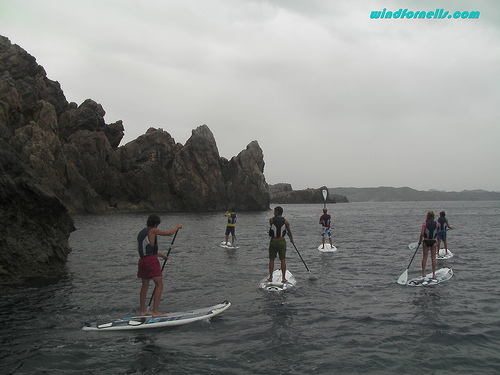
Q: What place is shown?
A: It is an ocean.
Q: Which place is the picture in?
A: It is at the ocean.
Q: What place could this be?
A: It is an ocean.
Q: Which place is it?
A: It is an ocean.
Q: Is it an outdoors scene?
A: Yes, it is outdoors.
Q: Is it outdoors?
A: Yes, it is outdoors.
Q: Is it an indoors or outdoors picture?
A: It is outdoors.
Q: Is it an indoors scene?
A: No, it is outdoors.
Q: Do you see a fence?
A: No, there are no fences.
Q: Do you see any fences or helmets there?
A: No, there are no fences or helmets.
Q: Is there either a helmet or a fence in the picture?
A: No, there are no fences or helmets.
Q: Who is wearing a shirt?
A: The man is wearing a shirt.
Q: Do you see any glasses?
A: No, there are no glasses.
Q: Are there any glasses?
A: No, there are no glasses.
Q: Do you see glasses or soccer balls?
A: No, there are no glasses or soccer balls.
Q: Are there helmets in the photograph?
A: No, there are no helmets.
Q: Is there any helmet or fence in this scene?
A: No, there are no helmets or fences.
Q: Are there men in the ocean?
A: Yes, there is a man in the ocean.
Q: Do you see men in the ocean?
A: Yes, there is a man in the ocean.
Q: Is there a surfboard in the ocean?
A: No, there is a man in the ocean.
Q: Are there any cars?
A: No, there are no cars.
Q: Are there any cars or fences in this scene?
A: No, there are no cars or fences.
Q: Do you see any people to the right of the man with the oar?
A: Yes, there are people to the right of the man.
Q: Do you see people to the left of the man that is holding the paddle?
A: No, the people are to the right of the man.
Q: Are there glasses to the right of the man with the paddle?
A: No, there are people to the right of the man.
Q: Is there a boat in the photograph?
A: No, there are no boats.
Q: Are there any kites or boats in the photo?
A: No, there are no boats or kites.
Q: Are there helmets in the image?
A: No, there are no helmets.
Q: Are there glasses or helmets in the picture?
A: No, there are no helmets or glasses.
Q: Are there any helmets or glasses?
A: No, there are no helmets or glasses.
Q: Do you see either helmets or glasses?
A: No, there are no helmets or glasses.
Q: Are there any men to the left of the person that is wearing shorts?
A: Yes, there is a man to the left of the person.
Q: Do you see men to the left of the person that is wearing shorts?
A: Yes, there is a man to the left of the person.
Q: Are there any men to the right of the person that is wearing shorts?
A: No, the man is to the left of the person.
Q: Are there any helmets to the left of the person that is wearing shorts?
A: No, there is a man to the left of the person.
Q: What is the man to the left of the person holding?
A: The man is holding the paddle.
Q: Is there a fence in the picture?
A: No, there are no fences.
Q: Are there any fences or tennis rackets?
A: No, there are no fences or tennis rackets.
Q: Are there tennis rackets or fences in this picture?
A: No, there are no fences or tennis rackets.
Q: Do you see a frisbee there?
A: No, there are no frisbees.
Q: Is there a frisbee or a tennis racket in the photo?
A: No, there are no frisbees or rackets.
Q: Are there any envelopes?
A: No, there are no envelopes.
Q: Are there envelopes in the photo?
A: No, there are no envelopes.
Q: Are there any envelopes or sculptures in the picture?
A: No, there are no envelopes or sculptures.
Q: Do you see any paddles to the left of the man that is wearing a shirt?
A: Yes, there is a paddle to the left of the man.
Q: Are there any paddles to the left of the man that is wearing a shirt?
A: Yes, there is a paddle to the left of the man.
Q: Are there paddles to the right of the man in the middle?
A: No, the paddle is to the left of the man.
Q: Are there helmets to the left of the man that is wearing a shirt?
A: No, there is a paddle to the left of the man.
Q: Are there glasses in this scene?
A: No, there are no glasses.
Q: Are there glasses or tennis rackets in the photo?
A: No, there are no glasses or tennis rackets.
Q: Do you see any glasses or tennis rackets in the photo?
A: No, there are no glasses or tennis rackets.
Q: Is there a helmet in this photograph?
A: No, there are no helmets.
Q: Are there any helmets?
A: No, there are no helmets.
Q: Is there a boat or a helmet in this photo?
A: No, there are no helmets or boats.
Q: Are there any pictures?
A: No, there are no pictures.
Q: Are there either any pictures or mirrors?
A: No, there are no pictures or mirrors.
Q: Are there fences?
A: No, there are no fences.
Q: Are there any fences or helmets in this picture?
A: No, there are no fences or helmets.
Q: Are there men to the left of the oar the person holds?
A: Yes, there is a man to the left of the oar.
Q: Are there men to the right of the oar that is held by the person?
A: No, the man is to the left of the oar.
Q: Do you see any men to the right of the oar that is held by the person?
A: No, the man is to the left of the oar.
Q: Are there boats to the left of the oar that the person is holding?
A: No, there is a man to the left of the paddle.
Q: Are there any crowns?
A: No, there are no crowns.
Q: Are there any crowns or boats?
A: No, there are no crowns or boats.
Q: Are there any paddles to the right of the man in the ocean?
A: Yes, there is a paddle to the right of the man.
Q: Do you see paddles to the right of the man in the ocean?
A: Yes, there is a paddle to the right of the man.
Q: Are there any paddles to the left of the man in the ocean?
A: No, the paddle is to the right of the man.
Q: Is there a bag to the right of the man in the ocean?
A: No, there is a paddle to the right of the man.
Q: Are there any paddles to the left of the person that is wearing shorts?
A: Yes, there is a paddle to the left of the person.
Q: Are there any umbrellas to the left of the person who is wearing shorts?
A: No, there is a paddle to the left of the person.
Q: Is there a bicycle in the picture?
A: No, there are no bicycles.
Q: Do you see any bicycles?
A: No, there are no bicycles.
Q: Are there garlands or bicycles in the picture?
A: No, there are no bicycles or garlands.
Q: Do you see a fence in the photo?
A: No, there are no fences.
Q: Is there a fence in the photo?
A: No, there are no fences.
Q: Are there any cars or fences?
A: No, there are no fences or cars.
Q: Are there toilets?
A: No, there are no toilets.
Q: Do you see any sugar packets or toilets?
A: No, there are no toilets or sugar packets.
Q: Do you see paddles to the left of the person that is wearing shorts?
A: Yes, there is a paddle to the left of the person.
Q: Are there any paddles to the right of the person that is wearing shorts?
A: No, the paddle is to the left of the person.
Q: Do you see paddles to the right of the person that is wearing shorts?
A: No, the paddle is to the left of the person.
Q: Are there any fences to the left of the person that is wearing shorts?
A: No, there is a paddle to the left of the person.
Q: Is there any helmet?
A: No, there are no helmets.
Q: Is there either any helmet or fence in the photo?
A: No, there are no helmets or fences.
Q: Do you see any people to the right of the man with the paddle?
A: Yes, there is a person to the right of the man.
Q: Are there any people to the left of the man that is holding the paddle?
A: No, the person is to the right of the man.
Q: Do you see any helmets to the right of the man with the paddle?
A: No, there is a person to the right of the man.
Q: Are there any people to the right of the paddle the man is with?
A: Yes, there is a person to the right of the oar.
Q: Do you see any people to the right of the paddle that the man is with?
A: Yes, there is a person to the right of the oar.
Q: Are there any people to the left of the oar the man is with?
A: No, the person is to the right of the paddle.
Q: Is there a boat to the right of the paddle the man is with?
A: No, there is a person to the right of the paddle.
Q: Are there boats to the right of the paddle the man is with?
A: No, there is a person to the right of the paddle.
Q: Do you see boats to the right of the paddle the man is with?
A: No, there is a person to the right of the paddle.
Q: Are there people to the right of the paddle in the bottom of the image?
A: Yes, there is a person to the right of the oar.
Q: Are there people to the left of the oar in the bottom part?
A: No, the person is to the right of the oar.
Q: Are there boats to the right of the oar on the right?
A: No, there is a person to the right of the oar.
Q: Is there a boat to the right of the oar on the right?
A: No, there is a person to the right of the oar.